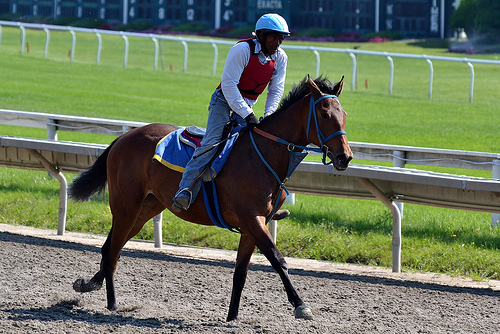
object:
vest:
[216, 37, 275, 101]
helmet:
[255, 13, 291, 54]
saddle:
[151, 126, 241, 183]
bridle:
[252, 94, 346, 165]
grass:
[0, 23, 499, 279]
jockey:
[170, 13, 290, 220]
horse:
[66, 73, 352, 322]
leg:
[103, 192, 146, 298]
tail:
[67, 138, 119, 205]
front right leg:
[238, 214, 299, 302]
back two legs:
[100, 191, 162, 298]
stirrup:
[172, 188, 192, 211]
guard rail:
[1, 20, 500, 103]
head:
[305, 74, 353, 171]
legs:
[101, 200, 163, 279]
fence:
[0, 109, 500, 273]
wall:
[0, 1, 449, 33]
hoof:
[73, 279, 103, 292]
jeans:
[176, 88, 251, 204]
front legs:
[229, 228, 255, 307]